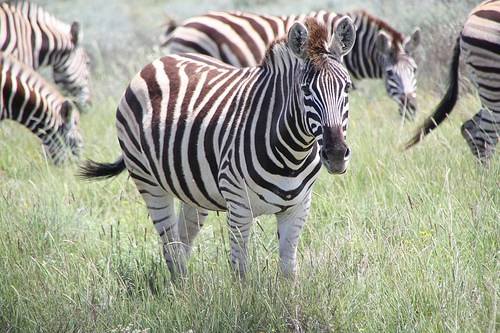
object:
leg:
[216, 173, 249, 284]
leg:
[274, 190, 314, 280]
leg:
[125, 164, 188, 281]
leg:
[177, 200, 209, 257]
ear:
[286, 21, 312, 59]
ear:
[329, 15, 357, 57]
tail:
[75, 153, 126, 188]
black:
[255, 129, 266, 152]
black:
[15, 95, 22, 108]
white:
[281, 220, 294, 234]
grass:
[1, 1, 500, 333]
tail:
[399, 32, 463, 150]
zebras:
[0, 0, 94, 115]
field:
[0, 0, 500, 333]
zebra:
[394, 0, 500, 167]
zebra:
[75, 16, 360, 298]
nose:
[321, 142, 353, 163]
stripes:
[128, 171, 158, 187]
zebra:
[0, 53, 83, 167]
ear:
[403, 29, 422, 54]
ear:
[374, 29, 394, 55]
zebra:
[160, 7, 420, 121]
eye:
[299, 85, 312, 94]